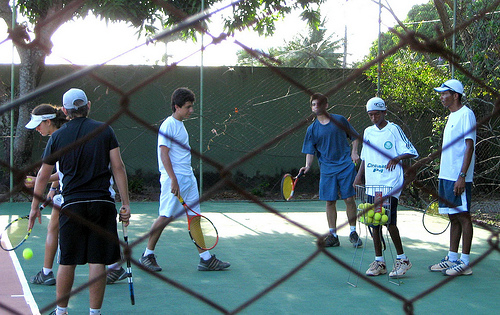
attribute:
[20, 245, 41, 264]
ball — green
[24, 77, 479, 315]
people — standing, ready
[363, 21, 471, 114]
plant — green, sided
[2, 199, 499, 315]
ground — grey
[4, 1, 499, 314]
fence — brown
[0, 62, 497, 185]
wall — white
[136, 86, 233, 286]
man — walking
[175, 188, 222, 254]
racket — red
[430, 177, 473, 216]
shorts — blue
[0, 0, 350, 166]
tree — growing, tall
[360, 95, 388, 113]
cap — backwards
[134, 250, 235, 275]
shoes — gray, paired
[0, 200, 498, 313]
court — green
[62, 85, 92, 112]
hat — white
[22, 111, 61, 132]
visor — white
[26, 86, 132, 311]
man — facing